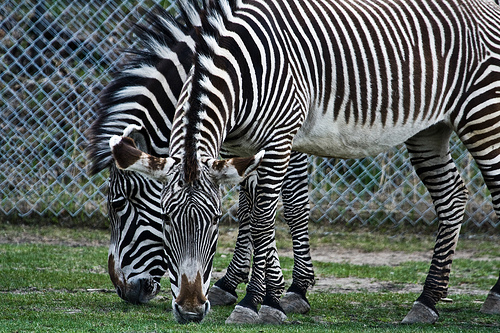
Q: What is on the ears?
A: Brown spots.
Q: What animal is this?
A: Zebra.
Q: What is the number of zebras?
A: 2.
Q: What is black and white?
A: The zebra pattern.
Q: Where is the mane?
A: On the zebra.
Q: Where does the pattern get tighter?
A: On the leg.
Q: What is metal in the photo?
A: The fence.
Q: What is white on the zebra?
A: It's stomach.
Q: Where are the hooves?
A: On the feet.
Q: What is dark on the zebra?
A: Black stripe.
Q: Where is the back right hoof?
A: On the zebra.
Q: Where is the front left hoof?
A: On the zebra.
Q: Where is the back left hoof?
A: On the zebra.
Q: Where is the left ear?
A: On the zebra.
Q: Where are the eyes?
A: On the zebra.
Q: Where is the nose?
A: On the zebra.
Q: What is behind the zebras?
A: A fence.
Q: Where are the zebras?
A: On the grass.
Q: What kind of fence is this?
A: A chain link fence.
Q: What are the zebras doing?
A: Eating.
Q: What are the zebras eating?
A: Grass.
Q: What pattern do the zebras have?
A: Stripes.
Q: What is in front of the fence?
A: Two zebras.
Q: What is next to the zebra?
A: Another zebra.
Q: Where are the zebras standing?
A: On the grass.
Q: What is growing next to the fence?
A: Grass.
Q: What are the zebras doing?
A: Eating.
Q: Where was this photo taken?
A: The zoo.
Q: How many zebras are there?
A: 2.